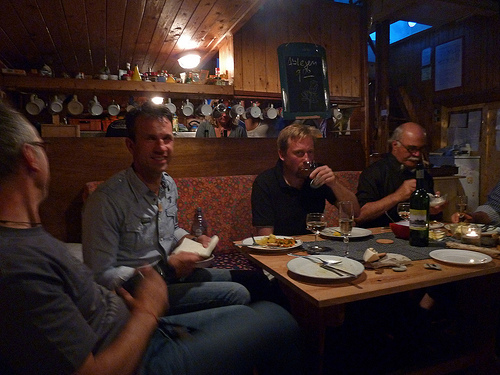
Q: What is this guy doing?
A: Drinking.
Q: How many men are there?
A: Four.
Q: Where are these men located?
A: Restaurant.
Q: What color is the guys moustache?
A: Gray.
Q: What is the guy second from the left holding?
A: Napkin.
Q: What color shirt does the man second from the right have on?
A: Black.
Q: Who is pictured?
A: A group of men.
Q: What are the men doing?
A: Eating, drinking, and talking.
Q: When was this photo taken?
A: In the evening.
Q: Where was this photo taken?
A: At a bar and restaurant.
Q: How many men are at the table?
A: There are 4.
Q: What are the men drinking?
A: A bottle of wine.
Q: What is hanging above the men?
A: Coffee cups.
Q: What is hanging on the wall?
A: A chalkboard.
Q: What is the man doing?
A: Eating.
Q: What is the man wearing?
A: A shirt.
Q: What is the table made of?
A: Wood.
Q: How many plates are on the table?
A: 6.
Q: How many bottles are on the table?
A: 1.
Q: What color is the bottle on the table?
A: Green.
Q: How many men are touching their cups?
A: Two.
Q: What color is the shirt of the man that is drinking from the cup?
A: Black.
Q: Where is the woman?
A: Background.